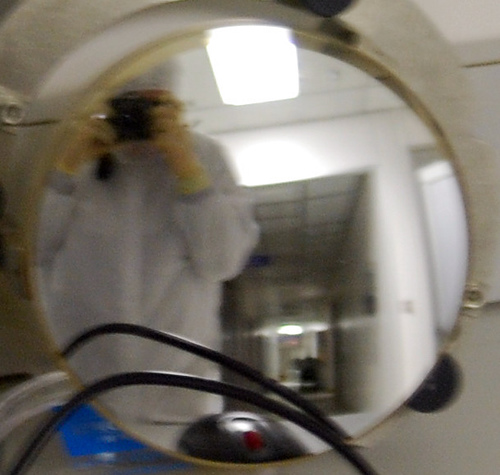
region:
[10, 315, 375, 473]
two thick black wires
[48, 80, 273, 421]
person holding a black camera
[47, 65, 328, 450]
person taking a photo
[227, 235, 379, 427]
long, white hallway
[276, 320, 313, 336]
bright light at the end of the hallway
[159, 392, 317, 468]
gray mouse with red on top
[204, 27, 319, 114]
bright light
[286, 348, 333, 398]
something in the hallway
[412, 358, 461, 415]
half of a black circle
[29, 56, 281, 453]
person wearing all white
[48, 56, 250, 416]
the reflection of a man in a white coat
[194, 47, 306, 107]
a bright white light reflecting in a mirror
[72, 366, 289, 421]
a black cord in front of a mirror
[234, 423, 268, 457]
a red button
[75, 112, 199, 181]
a pair of yellow gloves on a man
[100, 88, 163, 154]
a black camera in a man's hands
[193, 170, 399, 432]
the reflection of a hallway in a mirror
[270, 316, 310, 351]
a white light reflecting down the hallway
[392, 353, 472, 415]
a black button behind a mirror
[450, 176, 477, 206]
the gold trim around a mirror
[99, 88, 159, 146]
camera in a person's hands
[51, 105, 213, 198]
yellow gloved hands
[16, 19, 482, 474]
large round mirror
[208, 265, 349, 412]
long hallway behind a person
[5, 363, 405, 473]
black wire in front of a mirror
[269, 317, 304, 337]
light on ceiling of hallway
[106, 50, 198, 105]
white cap on person's head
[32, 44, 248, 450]
person in white taking picture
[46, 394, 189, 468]
blue item behind mirror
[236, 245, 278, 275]
blue sign hanging from ceiling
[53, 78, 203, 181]
a man taking a photograph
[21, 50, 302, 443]
a scientist working on an experiment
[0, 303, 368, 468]
medical equipment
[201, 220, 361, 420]
a hallway in a lab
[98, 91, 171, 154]
a camera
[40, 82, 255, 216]
gloves on a scientist's hands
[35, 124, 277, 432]
scrubs being worn by a scientist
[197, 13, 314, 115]
florescent light in a laboratory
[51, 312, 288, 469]
metal tubes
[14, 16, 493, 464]
an opening in a chamber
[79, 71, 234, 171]
Man with a camera.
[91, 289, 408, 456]
Cords in front of the man.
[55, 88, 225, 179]
Man with a black camera.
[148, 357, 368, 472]
Red part of the mirror.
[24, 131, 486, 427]
Mirror in front of the man.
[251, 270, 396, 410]
Hallway reflected in the mirror.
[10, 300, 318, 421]
Black cord in front.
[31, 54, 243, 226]
Man who has gloves.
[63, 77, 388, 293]
Yellow gloves on the man.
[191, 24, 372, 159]
Light on the ceiling.